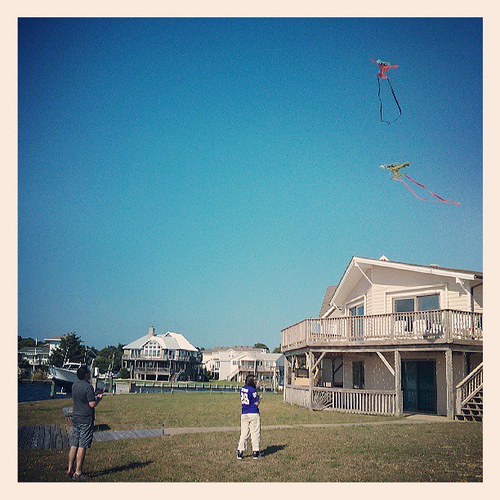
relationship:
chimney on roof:
[144, 325, 157, 337] [123, 334, 193, 350]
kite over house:
[370, 56, 402, 124] [269, 245, 482, 420]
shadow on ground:
[252, 444, 282, 459] [19, 376, 483, 483]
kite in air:
[378, 159, 461, 212] [348, 45, 430, 163]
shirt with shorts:
[73, 387, 103, 411] [57, 417, 112, 457]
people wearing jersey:
[238, 369, 265, 460] [236, 380, 260, 415]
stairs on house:
[434, 359, 487, 435] [269, 245, 482, 420]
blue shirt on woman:
[239, 386, 260, 414] [229, 370, 267, 470]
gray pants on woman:
[238, 412, 263, 449] [236, 368, 263, 460]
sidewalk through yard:
[20, 419, 450, 448] [18, 391, 483, 481]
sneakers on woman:
[234, 449, 262, 461] [228, 360, 273, 481]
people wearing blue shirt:
[238, 369, 265, 460] [239, 382, 261, 413]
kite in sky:
[370, 56, 399, 128] [18, 18, 480, 352]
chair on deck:
[399, 307, 416, 333] [276, 320, 480, 355]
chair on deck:
[417, 314, 437, 340] [276, 320, 480, 355]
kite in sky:
[370, 56, 402, 124] [18, 18, 480, 352]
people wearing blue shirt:
[238, 369, 265, 460] [234, 374, 269, 413]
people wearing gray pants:
[238, 369, 265, 460] [229, 409, 281, 458]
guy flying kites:
[64, 365, 106, 485] [355, 49, 483, 236]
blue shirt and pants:
[239, 386, 260, 414] [236, 407, 264, 456]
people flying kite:
[237, 368, 273, 470] [359, 47, 426, 184]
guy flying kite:
[64, 365, 106, 485] [359, 47, 426, 184]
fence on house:
[282, 380, 396, 417] [320, 255, 482, 425]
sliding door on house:
[398, 357, 442, 414] [278, 254, 482, 423]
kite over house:
[370, 56, 402, 124] [278, 254, 482, 423]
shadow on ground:
[86, 454, 151, 477] [19, 376, 483, 483]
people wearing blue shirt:
[238, 369, 265, 460] [239, 386, 260, 414]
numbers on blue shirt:
[240, 391, 250, 407] [239, 386, 260, 414]